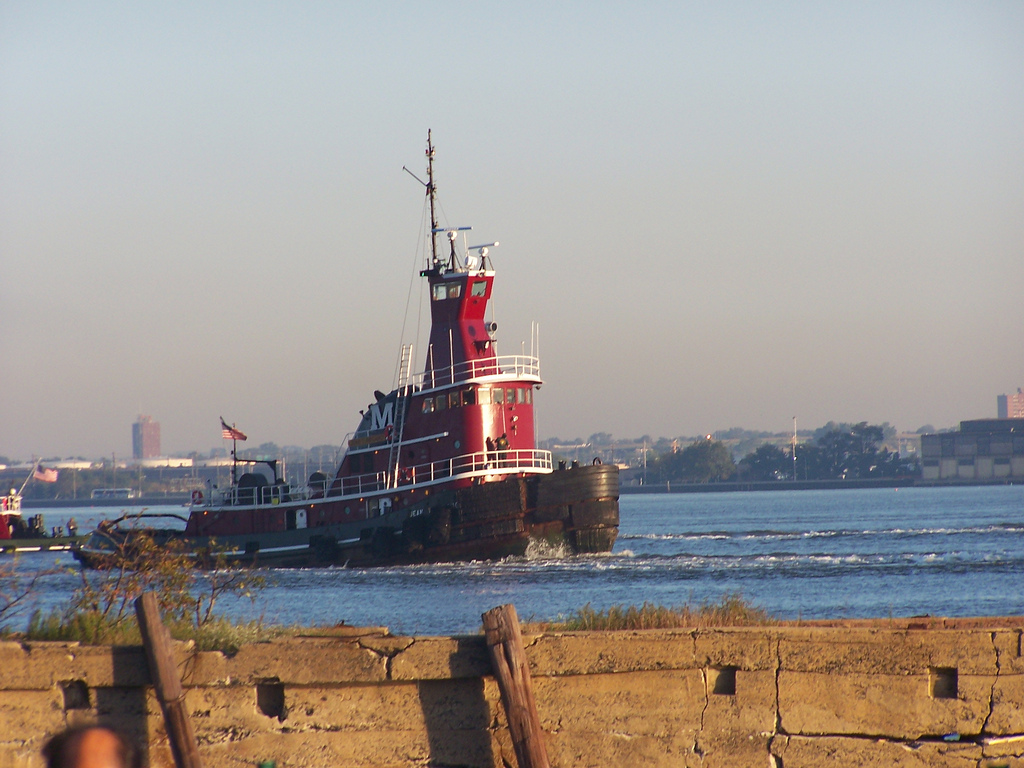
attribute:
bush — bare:
[65, 516, 266, 637]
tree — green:
[43, 555, 258, 669]